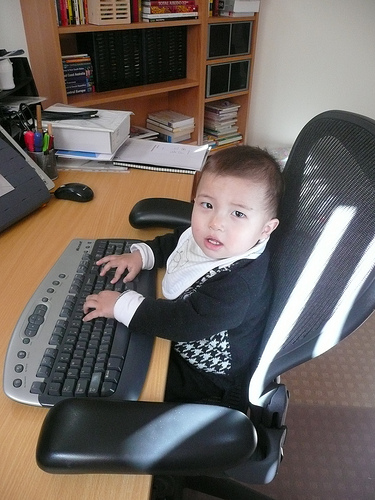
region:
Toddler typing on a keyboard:
[2, 144, 284, 408]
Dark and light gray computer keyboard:
[5, 236, 155, 407]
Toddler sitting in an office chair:
[2, 107, 373, 497]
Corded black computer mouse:
[50, 182, 93, 202]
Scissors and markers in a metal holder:
[9, 101, 56, 180]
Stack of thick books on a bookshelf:
[60, 52, 93, 95]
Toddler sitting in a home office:
[1, 0, 374, 498]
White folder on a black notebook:
[113, 138, 211, 174]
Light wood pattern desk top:
[0, 161, 194, 498]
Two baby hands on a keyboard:
[79, 242, 142, 328]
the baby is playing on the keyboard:
[4, 121, 295, 412]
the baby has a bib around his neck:
[156, 143, 274, 322]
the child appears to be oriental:
[177, 152, 293, 269]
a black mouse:
[54, 173, 99, 216]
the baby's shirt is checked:
[165, 257, 246, 380]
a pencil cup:
[15, 98, 83, 180]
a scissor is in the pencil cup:
[5, 100, 43, 152]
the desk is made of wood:
[45, 211, 130, 233]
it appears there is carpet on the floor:
[310, 368, 373, 467]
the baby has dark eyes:
[178, 187, 254, 237]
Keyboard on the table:
[11, 324, 126, 395]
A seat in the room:
[33, 395, 280, 473]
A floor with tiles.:
[290, 386, 360, 465]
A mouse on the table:
[53, 178, 94, 204]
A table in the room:
[146, 107, 192, 143]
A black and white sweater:
[138, 258, 277, 373]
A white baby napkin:
[158, 239, 199, 297]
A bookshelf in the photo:
[32, 0, 258, 136]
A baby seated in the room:
[83, 146, 287, 406]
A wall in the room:
[266, 4, 359, 108]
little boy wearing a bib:
[196, 160, 258, 373]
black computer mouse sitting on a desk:
[55, 183, 96, 201]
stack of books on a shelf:
[204, 103, 245, 143]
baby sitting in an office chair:
[190, 161, 271, 333]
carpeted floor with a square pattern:
[298, 371, 368, 485]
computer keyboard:
[23, 325, 121, 393]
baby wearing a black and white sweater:
[200, 158, 273, 401]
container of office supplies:
[21, 106, 56, 171]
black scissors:
[10, 107, 35, 128]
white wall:
[268, 4, 367, 104]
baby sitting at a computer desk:
[0, 2, 374, 498]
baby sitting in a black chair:
[153, 70, 372, 498]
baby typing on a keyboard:
[0, 149, 326, 464]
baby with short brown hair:
[69, 125, 302, 412]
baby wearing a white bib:
[81, 142, 308, 413]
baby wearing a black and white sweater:
[70, 135, 318, 432]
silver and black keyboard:
[1, 211, 162, 418]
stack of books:
[203, 95, 249, 147]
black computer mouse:
[50, 174, 96, 206]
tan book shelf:
[13, 0, 279, 161]